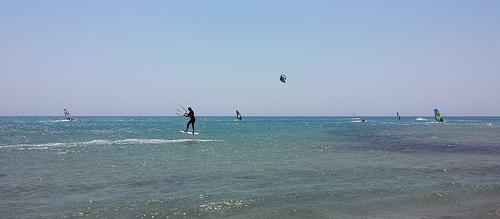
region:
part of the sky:
[163, 9, 216, 34]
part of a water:
[256, 120, 288, 143]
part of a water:
[263, 129, 317, 181]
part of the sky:
[207, 47, 284, 107]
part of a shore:
[246, 145, 314, 194]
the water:
[262, 151, 279, 186]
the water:
[347, 190, 357, 208]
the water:
[328, 170, 352, 198]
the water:
[281, 142, 331, 212]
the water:
[267, 152, 311, 204]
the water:
[310, 172, 371, 212]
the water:
[290, 128, 372, 215]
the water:
[320, 134, 367, 204]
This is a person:
[172, 100, 199, 133]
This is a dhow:
[52, 101, 77, 126]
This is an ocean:
[0, 111, 498, 217]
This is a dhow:
[429, 106, 448, 124]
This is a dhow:
[393, 102, 401, 123]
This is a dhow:
[343, 94, 372, 138]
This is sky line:
[2, 1, 499, 113]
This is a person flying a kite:
[165, 71, 310, 135]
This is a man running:
[166, 93, 210, 140]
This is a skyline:
[4, 81, 499, 158]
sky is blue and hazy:
[35, 15, 131, 75]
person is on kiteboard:
[155, 93, 223, 145]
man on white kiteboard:
[172, 105, 211, 143]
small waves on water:
[112, 115, 211, 152]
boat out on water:
[232, 101, 253, 131]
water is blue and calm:
[260, 114, 363, 192]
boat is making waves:
[52, 105, 75, 123]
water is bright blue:
[262, 115, 382, 197]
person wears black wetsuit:
[175, 105, 209, 136]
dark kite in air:
[273, 58, 293, 89]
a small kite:
[278, 72, 284, 83]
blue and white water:
[0, 115, 495, 215]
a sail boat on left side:
[60, 105, 75, 125]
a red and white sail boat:
[232, 106, 238, 121]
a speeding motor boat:
[357, 115, 364, 122]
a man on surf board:
[180, 105, 197, 135]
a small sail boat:
[392, 107, 399, 117]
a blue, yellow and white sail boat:
[430, 105, 441, 125]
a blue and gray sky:
[0, 0, 498, 115]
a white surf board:
[176, 125, 201, 135]